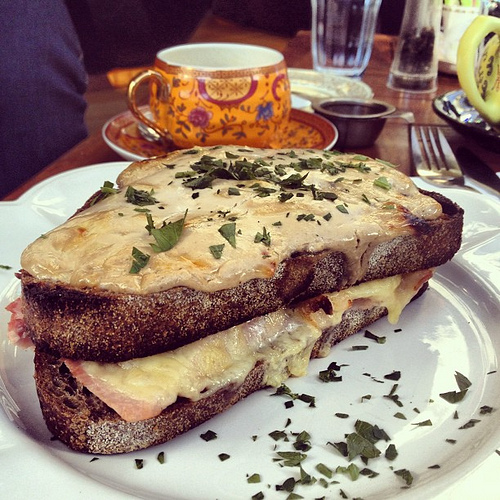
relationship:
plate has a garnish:
[3, 249, 496, 499] [349, 419, 399, 462]